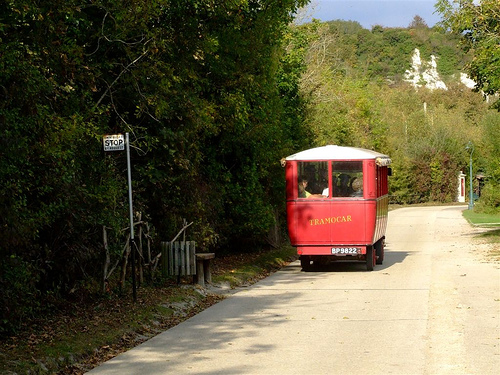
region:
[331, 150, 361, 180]
part of a window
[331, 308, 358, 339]
part of a line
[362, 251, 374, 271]
part of a wheel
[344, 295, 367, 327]
part of a floor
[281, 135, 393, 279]
red train car on road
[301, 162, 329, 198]
left window on car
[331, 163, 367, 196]
right window on car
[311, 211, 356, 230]
yellow writing printed on car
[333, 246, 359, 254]
license plate number of car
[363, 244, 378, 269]
black wheel on the car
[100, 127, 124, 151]
white and black bus stop sign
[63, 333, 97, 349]
green grass on the ground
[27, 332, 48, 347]
leaves on the ground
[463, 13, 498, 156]
green tree on side of road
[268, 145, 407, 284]
red and white vehicle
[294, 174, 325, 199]
someone sitting in the vehicle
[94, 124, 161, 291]
small sign on the side of the road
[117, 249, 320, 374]
shadows on the road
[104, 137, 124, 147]
black writing in all caps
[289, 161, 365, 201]
two windows on the back of the vehicle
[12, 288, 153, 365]
leaves on the grass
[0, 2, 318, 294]
thick green trees along the side of the road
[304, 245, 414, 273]
shadow from the vehicle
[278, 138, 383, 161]
roof is white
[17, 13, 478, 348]
a small red bus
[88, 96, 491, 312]
a small red trolly car on the road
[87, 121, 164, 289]
a sign for traffic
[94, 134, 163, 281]
this sign has the word stop on it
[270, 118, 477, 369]
a road for traveling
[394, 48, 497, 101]
white structures in the background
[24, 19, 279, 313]
trees along the side of the road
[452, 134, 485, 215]
a green pole in the distance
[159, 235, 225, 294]
a garbage can in the picture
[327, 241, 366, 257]
the license plate on the vehicle